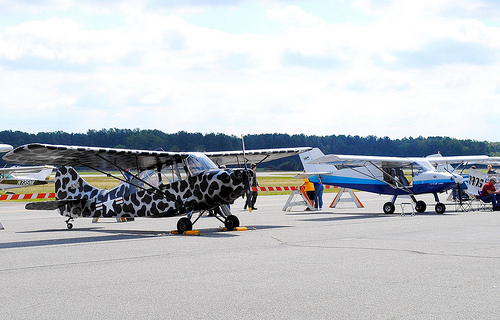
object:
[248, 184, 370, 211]
barricade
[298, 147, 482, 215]
airplane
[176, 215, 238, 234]
black wheels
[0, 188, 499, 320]
floor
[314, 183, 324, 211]
people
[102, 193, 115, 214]
star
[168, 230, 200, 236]
chocks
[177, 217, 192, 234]
wheel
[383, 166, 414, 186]
door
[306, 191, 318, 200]
shorts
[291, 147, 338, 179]
tail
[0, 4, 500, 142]
clouds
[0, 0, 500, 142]
sky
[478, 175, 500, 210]
man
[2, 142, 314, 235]
airplane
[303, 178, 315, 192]
shirt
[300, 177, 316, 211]
person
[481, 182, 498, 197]
shirt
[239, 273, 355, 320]
part